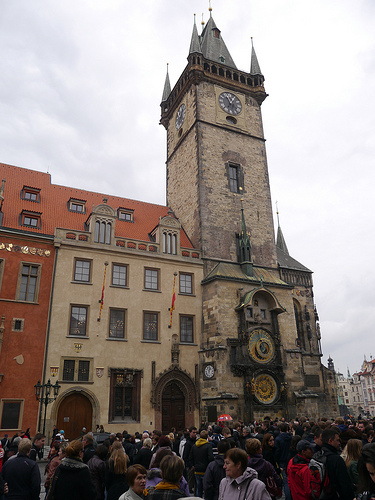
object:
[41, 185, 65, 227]
tiles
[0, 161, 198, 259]
roof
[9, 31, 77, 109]
clouds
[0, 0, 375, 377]
sky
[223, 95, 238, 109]
clock face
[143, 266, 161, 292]
window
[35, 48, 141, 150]
clouds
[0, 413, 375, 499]
crowd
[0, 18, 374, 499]
scene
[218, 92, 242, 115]
clock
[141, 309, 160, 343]
window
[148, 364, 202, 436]
doorway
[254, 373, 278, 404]
clock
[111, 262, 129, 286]
windows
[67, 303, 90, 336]
windows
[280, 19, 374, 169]
clouds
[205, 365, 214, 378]
clock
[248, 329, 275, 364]
clock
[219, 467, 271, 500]
coat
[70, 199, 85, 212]
window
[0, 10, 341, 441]
building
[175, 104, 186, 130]
clock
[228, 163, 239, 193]
window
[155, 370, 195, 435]
door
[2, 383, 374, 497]
town square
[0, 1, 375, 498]
czech republic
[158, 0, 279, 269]
tower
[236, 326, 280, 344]
apostles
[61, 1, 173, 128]
clouds